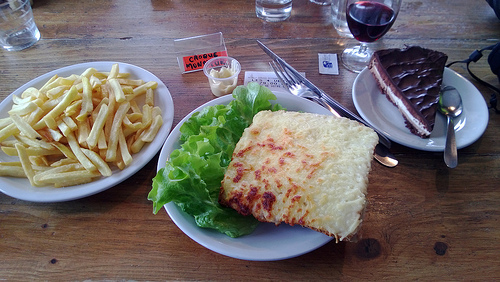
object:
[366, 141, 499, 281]
ground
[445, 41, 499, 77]
black wire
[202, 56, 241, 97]
small container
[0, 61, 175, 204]
plate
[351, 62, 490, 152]
plate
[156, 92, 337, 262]
plate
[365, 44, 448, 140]
food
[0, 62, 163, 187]
food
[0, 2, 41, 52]
bottle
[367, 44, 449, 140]
cake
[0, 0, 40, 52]
empty glass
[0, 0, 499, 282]
table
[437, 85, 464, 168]
spoon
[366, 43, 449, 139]
pie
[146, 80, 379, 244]
food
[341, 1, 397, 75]
glass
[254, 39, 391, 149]
knife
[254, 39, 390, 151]
metal fork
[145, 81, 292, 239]
lettuce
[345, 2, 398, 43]
beer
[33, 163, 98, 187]
french fry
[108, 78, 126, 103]
french fry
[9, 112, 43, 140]
french fry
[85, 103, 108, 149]
french fry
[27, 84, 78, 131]
french fry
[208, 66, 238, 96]
condiment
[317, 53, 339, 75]
salt package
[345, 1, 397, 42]
wine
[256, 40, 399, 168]
fork